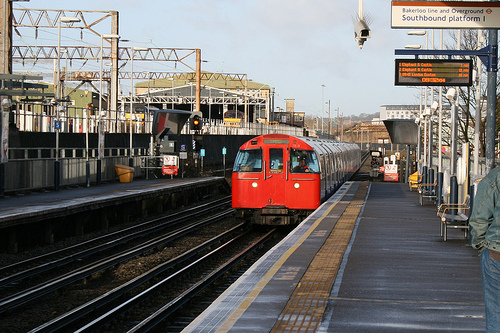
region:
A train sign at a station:
[390, 41, 497, 103]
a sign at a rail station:
[389, 43, 483, 105]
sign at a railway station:
[387, 41, 487, 108]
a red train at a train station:
[208, 104, 433, 235]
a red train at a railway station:
[135, 44, 460, 261]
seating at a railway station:
[395, 152, 475, 251]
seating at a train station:
[399, 151, 476, 248]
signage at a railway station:
[385, 0, 497, 92]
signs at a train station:
[378, 2, 498, 216]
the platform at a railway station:
[189, 114, 496, 331]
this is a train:
[209, 84, 369, 226]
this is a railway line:
[51, 232, 143, 329]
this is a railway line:
[110, 240, 182, 321]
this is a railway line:
[189, 195, 212, 264]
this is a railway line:
[91, 232, 155, 287]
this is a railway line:
[164, 208, 217, 285]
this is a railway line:
[171, 190, 251, 272]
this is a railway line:
[126, 223, 204, 265]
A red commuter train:
[218, 127, 372, 231]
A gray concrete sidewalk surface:
[363, 213, 437, 331]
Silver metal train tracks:
[70, 237, 210, 330]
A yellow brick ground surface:
[291, 211, 351, 323]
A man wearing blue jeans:
[454, 128, 499, 332]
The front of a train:
[222, 128, 329, 233]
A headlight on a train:
[290, 180, 304, 190]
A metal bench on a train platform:
[432, 183, 482, 247]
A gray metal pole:
[188, 44, 206, 109]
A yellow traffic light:
[183, 110, 207, 133]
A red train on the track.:
[231, 127, 381, 220]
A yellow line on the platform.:
[291, 179, 352, 304]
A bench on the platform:
[428, 183, 475, 254]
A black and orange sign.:
[388, 35, 488, 107]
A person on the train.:
[287, 137, 323, 177]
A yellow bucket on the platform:
[113, 153, 143, 188]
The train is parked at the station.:
[31, 29, 486, 237]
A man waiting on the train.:
[465, 138, 499, 298]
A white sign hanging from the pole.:
[375, 6, 482, 41]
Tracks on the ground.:
[79, 218, 207, 304]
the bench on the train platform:
[432, 191, 477, 247]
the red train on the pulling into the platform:
[229, 134, 363, 216]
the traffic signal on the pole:
[186, 110, 203, 129]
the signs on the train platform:
[194, 143, 229, 170]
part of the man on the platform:
[455, 153, 498, 325]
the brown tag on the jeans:
[483, 242, 498, 263]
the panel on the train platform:
[379, 114, 428, 144]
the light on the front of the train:
[249, 178, 300, 191]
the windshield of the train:
[236, 147, 321, 179]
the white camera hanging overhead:
[343, 0, 374, 52]